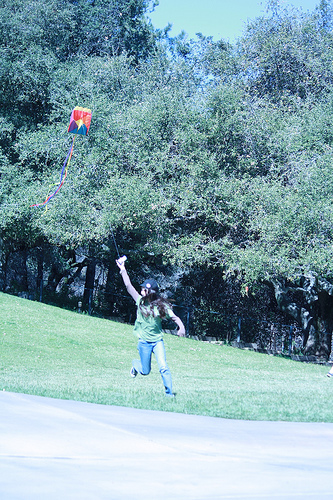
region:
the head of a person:
[130, 263, 167, 311]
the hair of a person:
[133, 261, 184, 320]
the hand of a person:
[104, 239, 156, 268]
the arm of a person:
[113, 232, 140, 318]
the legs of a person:
[123, 310, 230, 394]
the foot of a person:
[122, 352, 149, 402]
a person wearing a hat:
[129, 236, 198, 317]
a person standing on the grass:
[110, 260, 236, 400]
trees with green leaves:
[217, 194, 320, 270]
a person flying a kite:
[49, 7, 239, 369]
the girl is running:
[130, 270, 176, 388]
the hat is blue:
[140, 276, 157, 291]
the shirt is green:
[143, 323, 152, 333]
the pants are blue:
[140, 345, 150, 360]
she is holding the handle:
[113, 255, 128, 263]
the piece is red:
[74, 111, 79, 118]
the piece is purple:
[70, 124, 76, 128]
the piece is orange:
[85, 118, 90, 123]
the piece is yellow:
[77, 121, 81, 126]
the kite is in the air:
[60, 97, 105, 165]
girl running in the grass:
[112, 251, 194, 405]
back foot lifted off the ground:
[125, 359, 149, 383]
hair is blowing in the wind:
[135, 285, 178, 327]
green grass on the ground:
[0, 291, 332, 420]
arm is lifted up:
[110, 250, 149, 315]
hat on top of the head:
[138, 277, 167, 292]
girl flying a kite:
[28, 104, 219, 413]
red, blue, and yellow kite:
[29, 92, 105, 224]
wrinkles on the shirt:
[140, 323, 163, 340]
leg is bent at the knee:
[126, 350, 157, 383]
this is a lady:
[120, 241, 201, 413]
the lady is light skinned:
[122, 270, 139, 291]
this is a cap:
[141, 277, 156, 291]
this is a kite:
[58, 93, 95, 149]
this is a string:
[90, 176, 125, 232]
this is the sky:
[181, 2, 237, 29]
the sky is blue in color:
[194, 9, 236, 28]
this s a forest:
[92, 47, 330, 193]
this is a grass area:
[205, 359, 306, 408]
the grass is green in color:
[213, 355, 250, 383]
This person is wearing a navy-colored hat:
[149, 273, 166, 295]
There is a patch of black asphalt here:
[227, 433, 235, 457]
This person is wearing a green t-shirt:
[141, 301, 167, 359]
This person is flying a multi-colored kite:
[69, 103, 98, 149]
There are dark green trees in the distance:
[214, 137, 259, 220]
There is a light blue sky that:
[210, 7, 228, 37]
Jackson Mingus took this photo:
[67, 173, 257, 469]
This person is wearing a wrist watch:
[116, 264, 134, 293]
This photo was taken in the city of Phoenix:
[64, 106, 200, 332]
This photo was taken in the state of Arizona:
[74, 91, 271, 484]